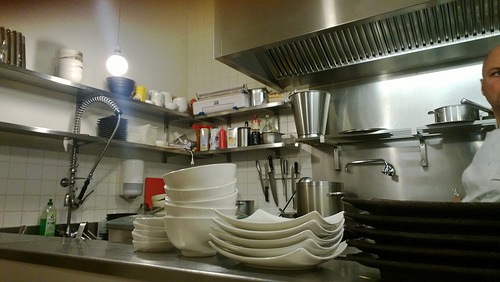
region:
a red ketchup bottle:
[217, 123, 228, 148]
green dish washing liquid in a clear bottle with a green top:
[38, 196, 58, 236]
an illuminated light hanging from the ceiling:
[102, 52, 129, 77]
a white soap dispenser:
[117, 156, 147, 200]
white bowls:
[160, 160, 241, 257]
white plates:
[207, 206, 349, 273]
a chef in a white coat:
[460, 43, 499, 202]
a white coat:
[458, 119, 498, 201]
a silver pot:
[293, 178, 343, 218]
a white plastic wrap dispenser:
[190, 82, 252, 117]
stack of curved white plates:
[229, 202, 326, 279]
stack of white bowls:
[160, 166, 227, 275]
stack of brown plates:
[351, 169, 496, 265]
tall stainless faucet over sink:
[67, 71, 102, 236]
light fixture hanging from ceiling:
[99, 45, 153, 82]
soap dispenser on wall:
[108, 150, 150, 227]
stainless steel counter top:
[71, 231, 130, 277]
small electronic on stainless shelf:
[188, 92, 276, 128]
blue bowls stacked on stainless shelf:
[109, 74, 137, 101]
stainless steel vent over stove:
[286, 15, 437, 103]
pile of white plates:
[207, 202, 347, 280]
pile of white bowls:
[157, 161, 241, 258]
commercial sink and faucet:
[57, 86, 124, 241]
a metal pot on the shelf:
[424, 101, 481, 128]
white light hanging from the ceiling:
[104, 2, 133, 82]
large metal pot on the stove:
[290, 176, 352, 230]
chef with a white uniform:
[460, 41, 499, 213]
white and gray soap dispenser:
[114, 154, 149, 207]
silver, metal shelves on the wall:
[1, 60, 309, 158]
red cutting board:
[141, 173, 169, 219]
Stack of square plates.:
[205, 184, 295, 272]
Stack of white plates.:
[230, 198, 320, 276]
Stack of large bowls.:
[156, 157, 237, 260]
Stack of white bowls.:
[163, 172, 246, 272]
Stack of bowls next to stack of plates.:
[171, 181, 296, 271]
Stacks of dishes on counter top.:
[119, 181, 257, 280]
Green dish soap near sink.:
[33, 190, 105, 265]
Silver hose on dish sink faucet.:
[67, 161, 139, 239]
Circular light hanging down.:
[103, 40, 165, 138]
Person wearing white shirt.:
[450, 156, 484, 193]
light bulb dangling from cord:
[102, 2, 131, 78]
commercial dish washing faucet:
[53, 90, 123, 222]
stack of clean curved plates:
[208, 204, 345, 272]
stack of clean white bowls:
[157, 161, 237, 257]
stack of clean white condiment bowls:
[130, 212, 173, 255]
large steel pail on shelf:
[287, 86, 332, 140]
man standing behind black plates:
[455, 37, 498, 204]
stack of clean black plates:
[341, 192, 498, 275]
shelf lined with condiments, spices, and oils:
[188, 114, 274, 151]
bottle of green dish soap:
[38, 196, 58, 236]